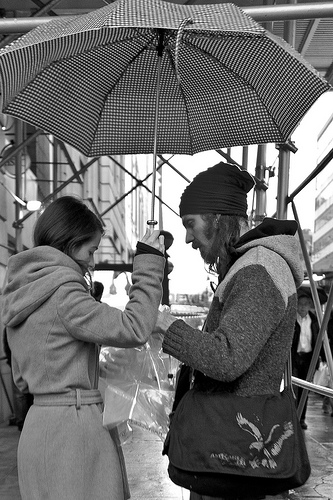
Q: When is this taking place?
A: Daytime.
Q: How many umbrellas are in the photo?
A: Two.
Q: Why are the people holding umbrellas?
A: To avoid getting wet.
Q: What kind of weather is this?
A: Rain.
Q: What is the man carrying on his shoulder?
A: Bag.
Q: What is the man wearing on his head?
A: Hat.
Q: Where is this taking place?
A: On a city sidewalk.